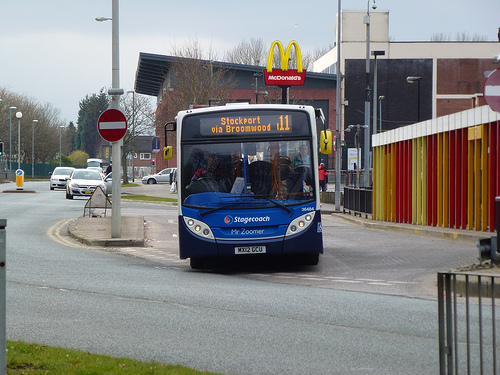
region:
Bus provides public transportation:
[159, 79, 377, 283]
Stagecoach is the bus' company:
[177, 209, 372, 282]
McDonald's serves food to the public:
[244, 41, 365, 114]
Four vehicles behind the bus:
[41, 146, 179, 207]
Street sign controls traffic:
[80, 86, 170, 182]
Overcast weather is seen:
[13, 36, 186, 138]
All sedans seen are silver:
[55, 160, 242, 214]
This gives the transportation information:
[185, 107, 345, 176]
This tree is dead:
[148, 45, 298, 122]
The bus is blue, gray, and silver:
[152, 110, 344, 273]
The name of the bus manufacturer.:
[220, 211, 276, 227]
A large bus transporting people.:
[161, 100, 336, 280]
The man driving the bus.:
[180, 145, 230, 200]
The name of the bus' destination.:
[180, 105, 300, 135]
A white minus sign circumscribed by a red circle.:
[90, 90, 126, 152]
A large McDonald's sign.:
[257, 30, 309, 86]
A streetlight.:
[90, 0, 130, 242]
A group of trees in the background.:
[5, 86, 105, 162]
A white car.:
[62, 165, 107, 201]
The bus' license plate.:
[230, 243, 271, 255]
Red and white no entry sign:
[97, 105, 129, 141]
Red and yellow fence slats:
[369, 108, 499, 230]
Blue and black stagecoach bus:
[172, 100, 323, 272]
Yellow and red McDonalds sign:
[265, 37, 315, 99]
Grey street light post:
[92, 0, 140, 243]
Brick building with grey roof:
[134, 46, 347, 184]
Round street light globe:
[15, 108, 25, 122]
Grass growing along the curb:
[5, 339, 208, 374]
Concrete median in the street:
[68, 204, 148, 249]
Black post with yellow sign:
[158, 117, 175, 173]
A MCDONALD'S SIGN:
[257, 37, 319, 97]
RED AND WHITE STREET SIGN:
[87, 105, 137, 150]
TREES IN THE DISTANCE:
[70, 82, 110, 157]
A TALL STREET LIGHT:
[397, 70, 432, 125]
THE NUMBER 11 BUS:
[150, 90, 350, 276]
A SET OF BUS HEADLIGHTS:
[170, 210, 320, 245]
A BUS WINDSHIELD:
[172, 130, 332, 200]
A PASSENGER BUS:
[159, 96, 334, 274]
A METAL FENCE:
[432, 256, 496, 371]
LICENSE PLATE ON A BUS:
[221, 237, 288, 264]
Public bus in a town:
[6, 6, 494, 355]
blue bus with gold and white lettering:
[168, 97, 335, 275]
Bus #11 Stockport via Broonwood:
[178, 96, 312, 148]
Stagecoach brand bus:
[185, 102, 315, 259]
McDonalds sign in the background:
[40, 12, 481, 287]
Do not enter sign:
[70, 80, 160, 255]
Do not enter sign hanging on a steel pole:
[71, 67, 132, 197]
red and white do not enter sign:
[85, 100, 145, 150]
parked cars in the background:
[30, 85, 430, 335]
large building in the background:
[30, 25, 496, 316]